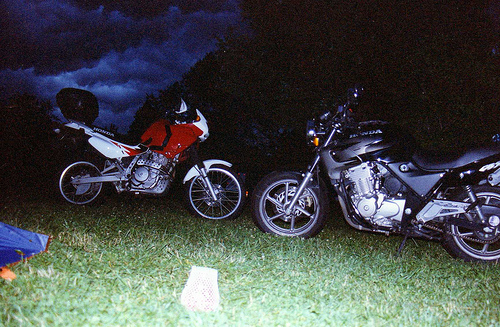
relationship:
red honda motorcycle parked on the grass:
[55, 88, 243, 222] [2, 87, 249, 325]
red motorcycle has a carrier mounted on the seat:
[55, 88, 243, 222] [55, 87, 100, 126]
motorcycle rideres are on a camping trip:
[250, 71, 499, 261] [1, 222, 52, 269]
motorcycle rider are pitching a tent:
[55, 88, 243, 222] [1, 222, 52, 269]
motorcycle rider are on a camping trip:
[55, 88, 243, 222] [1, 222, 52, 269]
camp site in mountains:
[1, 1, 498, 327] [1, 0, 499, 175]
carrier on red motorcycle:
[55, 87, 100, 126] [55, 88, 243, 222]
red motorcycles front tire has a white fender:
[55, 88, 243, 222] [183, 159, 233, 183]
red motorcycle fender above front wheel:
[55, 88, 243, 222] [183, 159, 244, 224]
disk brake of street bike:
[276, 189, 305, 220] [250, 71, 499, 261]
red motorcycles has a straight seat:
[55, 88, 243, 222] [83, 119, 139, 146]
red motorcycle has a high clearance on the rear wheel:
[55, 88, 243, 222] [57, 156, 105, 209]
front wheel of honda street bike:
[250, 171, 325, 242] [250, 71, 499, 261]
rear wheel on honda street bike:
[442, 188, 499, 261] [250, 71, 499, 261]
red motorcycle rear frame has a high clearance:
[55, 88, 243, 222] [52, 121, 104, 205]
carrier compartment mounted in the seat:
[55, 87, 100, 126] [56, 87, 129, 143]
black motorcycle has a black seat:
[250, 71, 499, 261] [410, 143, 498, 173]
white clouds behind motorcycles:
[1, 0, 245, 137] [55, 88, 243, 222]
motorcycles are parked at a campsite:
[250, 71, 499, 261] [1, 1, 498, 327]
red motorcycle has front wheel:
[55, 88, 243, 222] [185, 166, 246, 221]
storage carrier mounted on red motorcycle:
[55, 87, 100, 126] [55, 88, 243, 222]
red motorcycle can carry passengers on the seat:
[55, 88, 243, 222] [83, 119, 139, 146]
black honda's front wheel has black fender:
[250, 71, 499, 261] [280, 161, 330, 210]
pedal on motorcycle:
[388, 213, 420, 240] [250, 71, 499, 261]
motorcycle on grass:
[250, 71, 499, 261] [5, 197, 495, 324]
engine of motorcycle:
[117, 150, 178, 192] [43, 85, 250, 228]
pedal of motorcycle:
[111, 184, 136, 194] [39, 77, 249, 221]